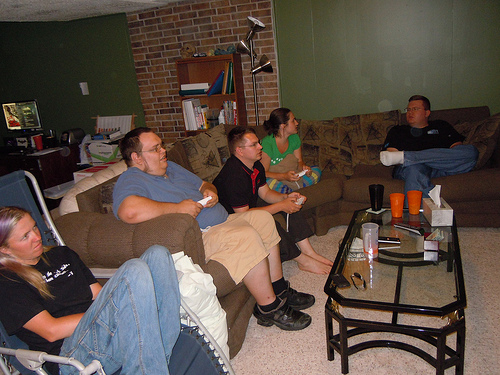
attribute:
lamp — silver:
[231, 11, 275, 129]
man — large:
[107, 130, 316, 329]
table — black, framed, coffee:
[346, 184, 488, 371]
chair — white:
[0, 167, 236, 373]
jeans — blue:
[92, 255, 179, 366]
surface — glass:
[328, 201, 471, 313]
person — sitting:
[378, 92, 480, 207]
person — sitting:
[259, 107, 321, 192]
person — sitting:
[210, 123, 335, 275]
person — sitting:
[110, 124, 316, 331]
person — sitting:
[0, 205, 181, 373]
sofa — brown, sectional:
[50, 100, 499, 352]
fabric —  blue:
[4, 168, 234, 373]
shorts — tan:
[201, 208, 282, 284]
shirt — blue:
[110, 158, 229, 229]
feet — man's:
[255, 272, 324, 343]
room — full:
[4, 41, 497, 372]